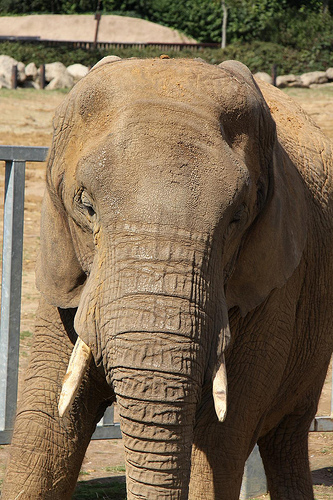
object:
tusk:
[213, 349, 228, 424]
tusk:
[56, 337, 91, 417]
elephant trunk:
[83, 177, 246, 496]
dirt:
[1, 83, 330, 498]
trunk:
[113, 254, 200, 496]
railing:
[5, 38, 225, 58]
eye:
[76, 192, 100, 221]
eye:
[221, 207, 245, 238]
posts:
[38, 63, 45, 89]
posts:
[11, 62, 18, 89]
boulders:
[14, 41, 97, 110]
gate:
[4, 129, 60, 375]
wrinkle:
[12, 408, 88, 456]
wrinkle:
[112, 389, 202, 410]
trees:
[239, 11, 259, 43]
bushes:
[241, 40, 300, 69]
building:
[27, 13, 198, 48]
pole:
[92, 19, 100, 54]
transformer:
[95, 10, 102, 20]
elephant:
[0, 55, 331, 498]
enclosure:
[0, 86, 331, 497]